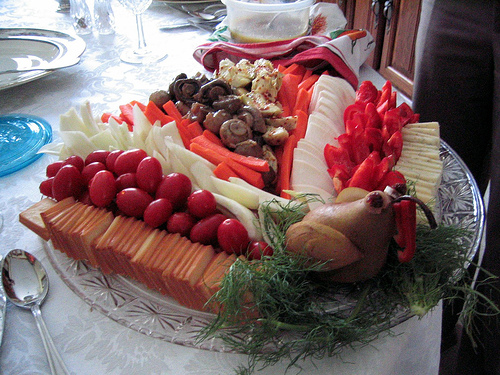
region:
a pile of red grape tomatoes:
[44, 147, 266, 256]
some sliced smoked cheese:
[21, 195, 256, 315]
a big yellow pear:
[294, 192, 436, 282]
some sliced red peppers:
[328, 80, 418, 201]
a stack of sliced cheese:
[397, 118, 444, 221]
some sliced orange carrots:
[184, 134, 270, 183]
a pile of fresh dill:
[224, 214, 481, 346]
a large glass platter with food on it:
[47, 68, 486, 351]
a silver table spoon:
[0, 250, 65, 374]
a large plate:
[0, 28, 85, 90]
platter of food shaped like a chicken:
[28, 19, 475, 349]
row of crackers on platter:
[381, 110, 447, 239]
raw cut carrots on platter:
[128, 97, 280, 175]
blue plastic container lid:
[0, 108, 59, 178]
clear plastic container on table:
[213, 3, 330, 51]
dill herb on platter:
[226, 221, 485, 338]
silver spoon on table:
[7, 238, 81, 373]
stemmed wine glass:
[98, 0, 184, 75]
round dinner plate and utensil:
[3, 11, 92, 105]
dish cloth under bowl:
[207, 10, 367, 82]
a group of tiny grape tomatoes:
[43, 155, 256, 260]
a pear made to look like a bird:
[292, 185, 414, 280]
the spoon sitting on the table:
[3, 250, 82, 372]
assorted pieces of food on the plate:
[156, 52, 291, 167]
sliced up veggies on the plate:
[268, 53, 401, 208]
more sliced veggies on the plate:
[69, 99, 284, 229]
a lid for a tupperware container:
[4, 113, 50, 175]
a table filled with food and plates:
[7, 2, 442, 372]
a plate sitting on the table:
[0, 24, 82, 91]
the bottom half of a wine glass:
[120, 0, 162, 72]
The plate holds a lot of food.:
[0, 42, 491, 359]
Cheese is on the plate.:
[13, 192, 278, 322]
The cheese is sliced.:
[5, 191, 275, 329]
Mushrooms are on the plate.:
[142, 68, 294, 160]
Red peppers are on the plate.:
[117, 99, 277, 186]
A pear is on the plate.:
[272, 174, 449, 290]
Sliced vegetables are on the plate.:
[52, 105, 291, 237]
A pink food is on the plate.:
[32, 142, 273, 260]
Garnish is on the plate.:
[211, 252, 384, 368]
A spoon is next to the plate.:
[0, 235, 68, 373]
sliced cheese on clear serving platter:
[6, 196, 258, 319]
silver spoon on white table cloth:
[2, 243, 69, 373]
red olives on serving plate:
[35, 143, 286, 276]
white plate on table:
[1, 23, 98, 96]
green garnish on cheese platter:
[206, 185, 498, 371]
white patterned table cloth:
[74, 313, 179, 374]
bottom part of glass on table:
[105, 3, 168, 70]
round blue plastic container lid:
[0, 106, 55, 182]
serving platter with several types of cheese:
[27, 43, 487, 357]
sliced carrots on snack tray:
[103, 94, 284, 195]